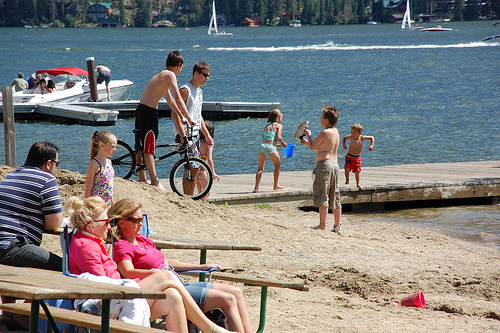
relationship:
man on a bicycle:
[134, 51, 192, 188] [96, 131, 214, 199]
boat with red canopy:
[0, 75, 134, 114] [35, 66, 92, 83]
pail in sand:
[402, 291, 429, 309] [70, 178, 499, 331]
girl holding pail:
[253, 109, 295, 198] [402, 291, 429, 309]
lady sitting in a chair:
[64, 193, 276, 331] [58, 228, 91, 331]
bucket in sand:
[282, 142, 299, 159] [70, 178, 499, 331]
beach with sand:
[3, 23, 498, 183] [70, 178, 499, 331]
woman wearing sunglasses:
[116, 202, 252, 332] [126, 215, 150, 228]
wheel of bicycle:
[171, 155, 214, 204] [96, 131, 214, 199]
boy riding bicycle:
[132, 47, 194, 194] [96, 131, 214, 199]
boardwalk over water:
[158, 160, 500, 209] [3, 23, 498, 183]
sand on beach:
[70, 178, 499, 331] [3, 164, 497, 332]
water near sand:
[370, 199, 499, 248] [2, 163, 498, 330]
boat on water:
[0, 75, 134, 114] [3, 23, 498, 183]